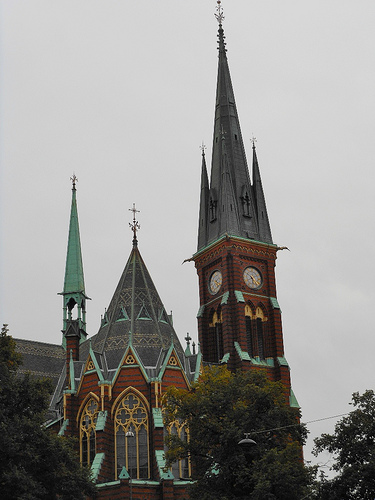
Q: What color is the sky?
A: Gray.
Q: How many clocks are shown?
A: 2.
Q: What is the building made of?
A: Brick.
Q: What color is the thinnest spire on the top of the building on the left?
A: Green.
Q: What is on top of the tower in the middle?
A: Cross.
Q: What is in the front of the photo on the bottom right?
A: Lamp.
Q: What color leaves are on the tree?
A: Green.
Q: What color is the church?
A: Red.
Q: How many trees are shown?
A: Three.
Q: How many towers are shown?
A: Three.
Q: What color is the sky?
A: Gray.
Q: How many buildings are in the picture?
A: One.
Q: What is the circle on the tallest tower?
A: A clock.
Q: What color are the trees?
A: Green.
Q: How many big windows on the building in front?
A: Three.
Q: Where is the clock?
A: Tallest tower.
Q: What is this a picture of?
A: A building.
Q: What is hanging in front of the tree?
A: A light.